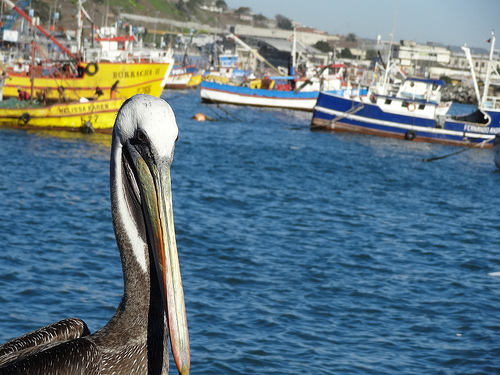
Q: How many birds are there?
A: One.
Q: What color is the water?
A: Blue.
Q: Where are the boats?
A: The water.